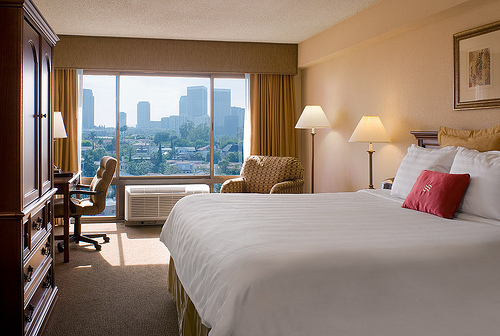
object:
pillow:
[432, 126, 499, 154]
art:
[453, 17, 499, 110]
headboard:
[408, 129, 440, 149]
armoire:
[2, 0, 63, 333]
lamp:
[291, 102, 331, 192]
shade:
[347, 113, 394, 147]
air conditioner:
[123, 181, 215, 224]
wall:
[115, 175, 320, 226]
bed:
[165, 125, 495, 334]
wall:
[291, 2, 497, 192]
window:
[75, 70, 253, 219]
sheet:
[159, 190, 499, 334]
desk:
[54, 163, 84, 269]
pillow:
[450, 144, 499, 220]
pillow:
[386, 143, 456, 206]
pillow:
[403, 168, 470, 220]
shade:
[295, 104, 335, 133]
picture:
[467, 47, 495, 86]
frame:
[453, 18, 499, 112]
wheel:
[55, 244, 65, 251]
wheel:
[104, 236, 109, 242]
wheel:
[95, 243, 102, 251]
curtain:
[52, 67, 80, 178]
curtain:
[248, 73, 303, 157]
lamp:
[53, 110, 78, 169]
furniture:
[12, 215, 69, 311]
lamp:
[351, 107, 391, 194]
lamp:
[60, 172, 81, 241]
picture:
[439, 19, 498, 115]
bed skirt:
[158, 284, 189, 324]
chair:
[221, 150, 306, 196]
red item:
[400, 163, 477, 216]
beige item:
[224, 154, 306, 196]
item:
[118, 177, 218, 221]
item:
[438, 122, 484, 150]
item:
[246, 70, 312, 165]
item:
[74, 70, 246, 185]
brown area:
[134, 272, 202, 333]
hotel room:
[0, 3, 499, 331]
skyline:
[81, 82, 247, 170]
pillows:
[390, 132, 499, 220]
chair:
[47, 151, 119, 262]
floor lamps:
[292, 105, 331, 130]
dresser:
[1, 5, 61, 334]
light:
[287, 99, 330, 189]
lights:
[352, 115, 393, 191]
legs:
[80, 236, 105, 250]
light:
[69, 208, 178, 276]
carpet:
[40, 212, 197, 333]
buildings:
[83, 88, 97, 136]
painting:
[446, 8, 498, 109]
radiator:
[120, 180, 215, 226]